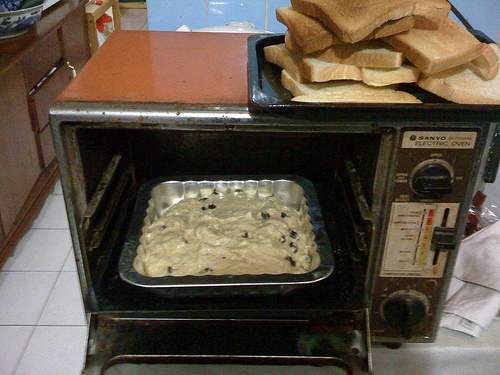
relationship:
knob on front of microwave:
[415, 156, 458, 203] [53, 28, 480, 291]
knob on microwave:
[415, 156, 458, 203] [53, 28, 480, 291]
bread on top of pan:
[255, 1, 497, 105] [241, 31, 499, 110]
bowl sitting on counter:
[1, 2, 40, 38] [2, 3, 85, 108]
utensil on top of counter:
[446, 193, 491, 302] [2, 3, 85, 108]